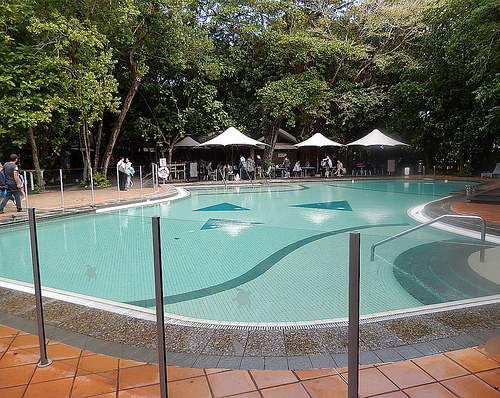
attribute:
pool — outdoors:
[1, 176, 500, 337]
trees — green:
[0, 4, 500, 178]